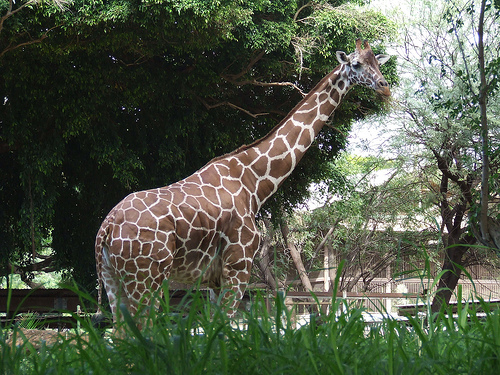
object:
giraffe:
[95, 39, 390, 346]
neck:
[214, 63, 354, 216]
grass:
[1, 217, 499, 374]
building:
[167, 157, 498, 314]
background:
[0, 1, 499, 326]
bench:
[397, 300, 498, 325]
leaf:
[266, 50, 269, 53]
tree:
[0, 0, 400, 288]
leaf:
[226, 30, 227, 31]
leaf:
[103, 18, 106, 20]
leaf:
[249, 12, 251, 14]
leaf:
[48, 13, 49, 16]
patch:
[178, 203, 196, 223]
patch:
[222, 178, 242, 194]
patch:
[139, 228, 155, 243]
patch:
[149, 198, 170, 217]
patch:
[185, 228, 208, 251]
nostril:
[380, 82, 383, 87]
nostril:
[384, 82, 387, 86]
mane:
[197, 63, 341, 184]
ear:
[335, 48, 350, 65]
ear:
[375, 50, 390, 64]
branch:
[292, 1, 327, 21]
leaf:
[314, 1, 316, 3]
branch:
[432, 55, 481, 104]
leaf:
[455, 70, 461, 76]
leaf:
[465, 86, 468, 90]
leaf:
[471, 96, 475, 100]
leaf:
[432, 56, 436, 60]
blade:
[405, 312, 433, 359]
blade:
[387, 320, 394, 374]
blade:
[300, 328, 318, 374]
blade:
[219, 340, 225, 374]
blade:
[73, 344, 98, 374]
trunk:
[422, 278, 459, 326]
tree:
[392, 0, 499, 324]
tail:
[94, 216, 110, 315]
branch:
[192, 91, 269, 123]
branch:
[0, 20, 64, 69]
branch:
[1, 0, 31, 30]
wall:
[0, 288, 208, 313]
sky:
[340, 0, 498, 158]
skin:
[95, 39, 390, 342]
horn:
[356, 39, 362, 51]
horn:
[362, 40, 368, 49]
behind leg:
[107, 235, 173, 356]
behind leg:
[101, 248, 129, 338]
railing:
[1, 289, 427, 299]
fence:
[0, 288, 429, 312]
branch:
[219, 72, 307, 98]